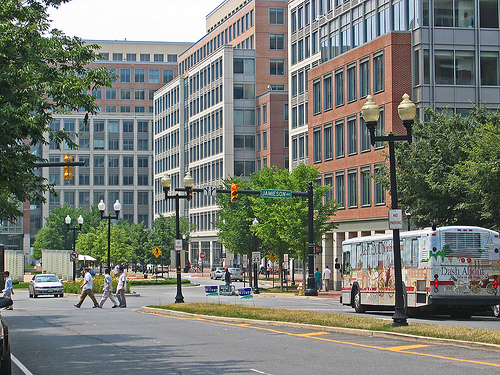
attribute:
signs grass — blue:
[195, 279, 286, 314]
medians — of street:
[168, 300, 498, 345]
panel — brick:
[308, 31, 417, 236]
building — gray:
[284, 0, 498, 252]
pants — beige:
[71, 287, 99, 309]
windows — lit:
[41, 109, 153, 225]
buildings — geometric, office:
[31, 34, 496, 267]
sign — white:
[377, 187, 420, 229]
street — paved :
[5, 287, 457, 373]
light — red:
[223, 178, 243, 206]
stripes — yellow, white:
[179, 311, 497, 363]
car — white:
[27, 257, 86, 310]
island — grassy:
[157, 297, 497, 342]